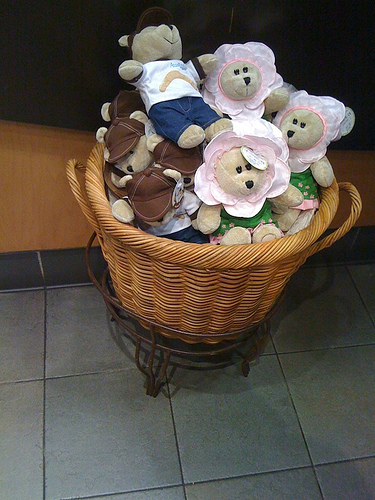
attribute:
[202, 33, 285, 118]
stuffed bear — cute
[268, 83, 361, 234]
bear — stuffed, cute